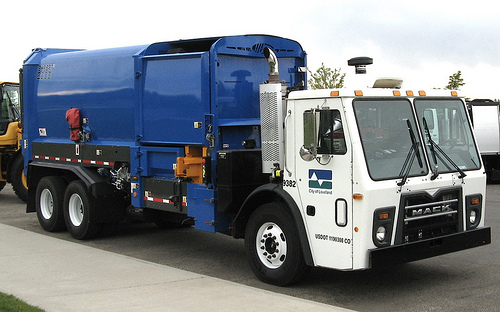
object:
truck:
[18, 34, 490, 286]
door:
[252, 96, 352, 271]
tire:
[244, 195, 302, 286]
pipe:
[257, 42, 285, 81]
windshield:
[338, 85, 486, 146]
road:
[15, 275, 254, 303]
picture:
[3, 24, 496, 288]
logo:
[307, 168, 336, 196]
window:
[351, 96, 483, 181]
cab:
[294, 90, 491, 268]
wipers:
[396, 116, 466, 187]